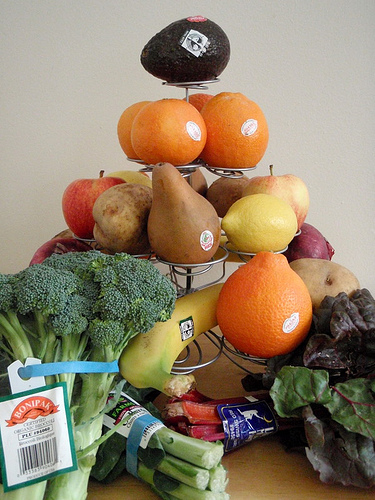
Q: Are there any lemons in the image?
A: Yes, there is a lemon.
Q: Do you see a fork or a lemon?
A: Yes, there is a lemon.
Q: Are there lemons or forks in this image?
A: Yes, there is a lemon.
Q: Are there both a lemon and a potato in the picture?
A: Yes, there are both a lemon and a potato.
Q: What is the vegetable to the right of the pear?
A: The vegetable is a lemon.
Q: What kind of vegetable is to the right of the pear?
A: The vegetable is a lemon.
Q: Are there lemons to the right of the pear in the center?
A: Yes, there is a lemon to the right of the pear.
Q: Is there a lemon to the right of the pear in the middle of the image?
A: Yes, there is a lemon to the right of the pear.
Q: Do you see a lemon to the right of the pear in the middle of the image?
A: Yes, there is a lemon to the right of the pear.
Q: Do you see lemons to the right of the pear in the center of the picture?
A: Yes, there is a lemon to the right of the pear.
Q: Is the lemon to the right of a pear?
A: Yes, the lemon is to the right of a pear.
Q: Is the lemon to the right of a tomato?
A: No, the lemon is to the right of a pear.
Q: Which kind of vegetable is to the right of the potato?
A: The vegetable is a lemon.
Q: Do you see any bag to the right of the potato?
A: No, there is a lemon to the right of the potato.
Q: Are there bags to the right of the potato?
A: No, there is a lemon to the right of the potato.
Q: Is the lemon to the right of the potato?
A: Yes, the lemon is to the right of the potato.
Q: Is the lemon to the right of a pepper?
A: No, the lemon is to the right of the potato.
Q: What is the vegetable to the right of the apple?
A: The vegetable is a lemon.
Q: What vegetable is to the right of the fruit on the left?
A: The vegetable is a lemon.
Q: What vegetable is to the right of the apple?
A: The vegetable is a lemon.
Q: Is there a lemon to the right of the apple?
A: Yes, there is a lemon to the right of the apple.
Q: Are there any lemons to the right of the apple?
A: Yes, there is a lemon to the right of the apple.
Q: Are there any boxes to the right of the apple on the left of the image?
A: No, there is a lemon to the right of the apple.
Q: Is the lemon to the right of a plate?
A: No, the lemon is to the right of an apple.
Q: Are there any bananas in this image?
A: Yes, there is a banana.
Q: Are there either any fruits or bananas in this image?
A: Yes, there is a banana.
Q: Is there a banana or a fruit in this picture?
A: Yes, there is a banana.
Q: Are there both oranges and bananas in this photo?
A: Yes, there are both a banana and oranges.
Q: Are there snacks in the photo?
A: No, there are no snacks.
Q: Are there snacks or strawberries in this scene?
A: No, there are no snacks or strawberries.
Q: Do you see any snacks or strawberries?
A: No, there are no snacks or strawberries.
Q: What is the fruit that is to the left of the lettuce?
A: The fruit is a banana.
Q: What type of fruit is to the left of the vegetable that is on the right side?
A: The fruit is a banana.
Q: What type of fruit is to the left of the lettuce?
A: The fruit is a banana.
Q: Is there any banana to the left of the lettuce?
A: Yes, there is a banana to the left of the lettuce.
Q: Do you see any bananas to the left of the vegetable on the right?
A: Yes, there is a banana to the left of the lettuce.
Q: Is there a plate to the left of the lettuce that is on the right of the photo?
A: No, there is a banana to the left of the lettuce.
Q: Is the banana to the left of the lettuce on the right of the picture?
A: Yes, the banana is to the left of the lettuce.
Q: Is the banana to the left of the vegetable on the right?
A: Yes, the banana is to the left of the lettuce.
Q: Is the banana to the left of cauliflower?
A: No, the banana is to the left of the lettuce.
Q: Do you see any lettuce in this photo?
A: Yes, there is lettuce.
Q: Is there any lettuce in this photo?
A: Yes, there is lettuce.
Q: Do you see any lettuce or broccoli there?
A: Yes, there is lettuce.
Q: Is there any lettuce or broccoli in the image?
A: Yes, there is lettuce.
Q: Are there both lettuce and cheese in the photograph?
A: No, there is lettuce but no cheese.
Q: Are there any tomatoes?
A: No, there are no tomatoes.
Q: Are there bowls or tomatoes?
A: No, there are no tomatoes or bowls.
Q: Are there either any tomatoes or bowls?
A: No, there are no tomatoes or bowls.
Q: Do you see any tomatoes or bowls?
A: No, there are no tomatoes or bowls.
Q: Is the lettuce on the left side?
A: No, the lettuce is on the right of the image.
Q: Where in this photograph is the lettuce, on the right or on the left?
A: The lettuce is on the right of the image.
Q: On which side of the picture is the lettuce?
A: The lettuce is on the right of the image.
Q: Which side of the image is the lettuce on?
A: The lettuce is on the right of the image.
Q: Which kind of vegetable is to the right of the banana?
A: The vegetable is lettuce.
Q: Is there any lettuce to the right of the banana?
A: Yes, there is lettuce to the right of the banana.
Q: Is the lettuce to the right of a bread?
A: No, the lettuce is to the right of the banana.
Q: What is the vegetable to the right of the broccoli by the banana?
A: The vegetable is lettuce.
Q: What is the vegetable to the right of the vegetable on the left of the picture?
A: The vegetable is lettuce.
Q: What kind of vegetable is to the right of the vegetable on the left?
A: The vegetable is lettuce.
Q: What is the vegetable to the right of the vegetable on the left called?
A: The vegetable is lettuce.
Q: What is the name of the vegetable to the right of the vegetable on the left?
A: The vegetable is lettuce.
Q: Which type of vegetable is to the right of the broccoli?
A: The vegetable is lettuce.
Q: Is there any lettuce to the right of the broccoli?
A: Yes, there is lettuce to the right of the broccoli.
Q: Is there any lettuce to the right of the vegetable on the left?
A: Yes, there is lettuce to the right of the broccoli.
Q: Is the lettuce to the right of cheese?
A: No, the lettuce is to the right of the broccoli.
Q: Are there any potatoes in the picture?
A: Yes, there is a potato.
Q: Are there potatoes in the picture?
A: Yes, there is a potato.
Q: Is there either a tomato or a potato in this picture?
A: Yes, there is a potato.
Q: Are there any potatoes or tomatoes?
A: Yes, there is a potato.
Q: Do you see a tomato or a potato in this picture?
A: Yes, there is a potato.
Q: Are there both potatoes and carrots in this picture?
A: No, there is a potato but no carrots.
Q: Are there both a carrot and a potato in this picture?
A: No, there is a potato but no carrots.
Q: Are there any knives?
A: No, there are no knives.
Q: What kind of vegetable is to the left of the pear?
A: The vegetable is a potato.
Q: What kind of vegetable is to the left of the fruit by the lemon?
A: The vegetable is a potato.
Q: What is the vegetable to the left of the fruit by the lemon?
A: The vegetable is a potato.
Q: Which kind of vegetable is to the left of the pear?
A: The vegetable is a potato.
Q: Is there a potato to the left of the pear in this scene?
A: Yes, there is a potato to the left of the pear.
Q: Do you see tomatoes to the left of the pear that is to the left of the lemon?
A: No, there is a potato to the left of the pear.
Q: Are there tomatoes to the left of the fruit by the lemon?
A: No, there is a potato to the left of the pear.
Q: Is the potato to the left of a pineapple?
A: No, the potato is to the left of a pear.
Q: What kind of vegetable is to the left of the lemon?
A: The vegetable is a potato.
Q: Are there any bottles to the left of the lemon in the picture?
A: No, there is a potato to the left of the lemon.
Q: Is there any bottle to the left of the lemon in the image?
A: No, there is a potato to the left of the lemon.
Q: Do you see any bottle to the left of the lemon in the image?
A: No, there is a potato to the left of the lemon.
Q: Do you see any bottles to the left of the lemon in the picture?
A: No, there is a potato to the left of the lemon.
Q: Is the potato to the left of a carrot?
A: No, the potato is to the left of the lemon.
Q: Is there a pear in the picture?
A: Yes, there is a pear.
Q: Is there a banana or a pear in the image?
A: Yes, there is a pear.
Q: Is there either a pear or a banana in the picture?
A: Yes, there is a pear.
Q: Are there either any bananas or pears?
A: Yes, there is a pear.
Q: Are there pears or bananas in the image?
A: Yes, there is a pear.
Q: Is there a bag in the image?
A: No, there are no bags.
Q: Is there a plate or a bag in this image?
A: No, there are no bags or plates.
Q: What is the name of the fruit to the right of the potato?
A: The fruit is a pear.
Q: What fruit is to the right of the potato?
A: The fruit is a pear.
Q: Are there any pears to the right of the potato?
A: Yes, there is a pear to the right of the potato.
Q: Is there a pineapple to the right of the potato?
A: No, there is a pear to the right of the potato.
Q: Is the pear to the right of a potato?
A: Yes, the pear is to the right of a potato.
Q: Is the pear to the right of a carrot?
A: No, the pear is to the right of a potato.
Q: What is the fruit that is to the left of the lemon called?
A: The fruit is a pear.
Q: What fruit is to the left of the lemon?
A: The fruit is a pear.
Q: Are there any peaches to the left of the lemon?
A: No, there is a pear to the left of the lemon.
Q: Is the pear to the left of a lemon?
A: Yes, the pear is to the left of a lemon.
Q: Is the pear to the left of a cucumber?
A: No, the pear is to the left of a lemon.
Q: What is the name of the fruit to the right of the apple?
A: The fruit is a pear.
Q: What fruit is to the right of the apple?
A: The fruit is a pear.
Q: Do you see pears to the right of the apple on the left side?
A: Yes, there is a pear to the right of the apple.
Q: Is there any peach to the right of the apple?
A: No, there is a pear to the right of the apple.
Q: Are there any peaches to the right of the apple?
A: No, there is a pear to the right of the apple.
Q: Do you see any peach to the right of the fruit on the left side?
A: No, there is a pear to the right of the apple.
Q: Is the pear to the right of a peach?
A: No, the pear is to the right of the apple.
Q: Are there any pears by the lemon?
A: Yes, there is a pear by the lemon.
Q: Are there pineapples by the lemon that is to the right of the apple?
A: No, there is a pear by the lemon.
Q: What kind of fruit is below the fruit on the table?
A: The fruit is a pear.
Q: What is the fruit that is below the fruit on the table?
A: The fruit is a pear.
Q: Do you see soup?
A: No, there is no soup.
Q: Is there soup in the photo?
A: No, there is no soup.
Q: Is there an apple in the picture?
A: Yes, there is an apple.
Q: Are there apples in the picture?
A: Yes, there is an apple.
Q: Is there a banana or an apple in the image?
A: Yes, there is an apple.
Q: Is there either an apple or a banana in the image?
A: Yes, there is an apple.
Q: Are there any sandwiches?
A: No, there are no sandwiches.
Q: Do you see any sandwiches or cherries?
A: No, there are no sandwiches or cherries.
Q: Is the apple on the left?
A: Yes, the apple is on the left of the image.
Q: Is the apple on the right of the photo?
A: No, the apple is on the left of the image.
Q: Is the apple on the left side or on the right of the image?
A: The apple is on the left of the image.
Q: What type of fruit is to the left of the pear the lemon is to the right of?
A: The fruit is an apple.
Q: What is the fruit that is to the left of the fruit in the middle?
A: The fruit is an apple.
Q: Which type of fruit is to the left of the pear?
A: The fruit is an apple.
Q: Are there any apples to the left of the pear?
A: Yes, there is an apple to the left of the pear.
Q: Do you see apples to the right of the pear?
A: No, the apple is to the left of the pear.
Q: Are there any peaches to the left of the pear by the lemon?
A: No, there is an apple to the left of the pear.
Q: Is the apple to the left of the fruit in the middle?
A: Yes, the apple is to the left of the pear.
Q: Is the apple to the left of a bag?
A: No, the apple is to the left of the pear.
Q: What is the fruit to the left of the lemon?
A: The fruit is an apple.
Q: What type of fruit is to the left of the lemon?
A: The fruit is an apple.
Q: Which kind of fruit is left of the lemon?
A: The fruit is an apple.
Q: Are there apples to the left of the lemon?
A: Yes, there is an apple to the left of the lemon.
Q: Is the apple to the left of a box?
A: No, the apple is to the left of the lemon.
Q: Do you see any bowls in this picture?
A: No, there are no bowls.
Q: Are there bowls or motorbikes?
A: No, there are no bowls or motorbikes.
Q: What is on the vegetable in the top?
A: The sticker is on the avocado.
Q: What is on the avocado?
A: The sticker is on the avocado.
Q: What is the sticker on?
A: The sticker is on the avocado.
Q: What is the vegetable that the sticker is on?
A: The vegetable is an avocado.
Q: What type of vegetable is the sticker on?
A: The sticker is on the avocado.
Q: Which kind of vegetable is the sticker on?
A: The sticker is on the avocado.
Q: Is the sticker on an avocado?
A: Yes, the sticker is on an avocado.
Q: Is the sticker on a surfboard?
A: No, the sticker is on an avocado.